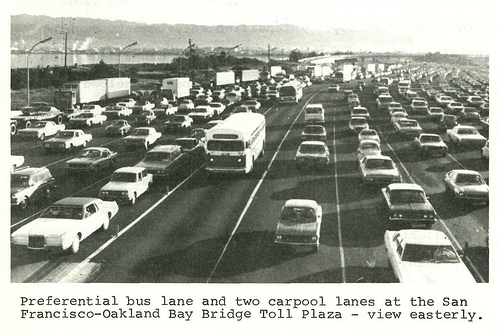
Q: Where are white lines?
A: On the street.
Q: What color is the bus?
A: White.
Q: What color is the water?
A: Gray.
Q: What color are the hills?
A: Gray.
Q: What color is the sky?
A: White.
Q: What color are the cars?
A: White.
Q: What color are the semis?
A: White.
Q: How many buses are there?
A: One.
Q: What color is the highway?
A: Gray.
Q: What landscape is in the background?
A: Mountains.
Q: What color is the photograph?
A: Black and white.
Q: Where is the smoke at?
A: Distant left.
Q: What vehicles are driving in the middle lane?
A: Busses.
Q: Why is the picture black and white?
A: Old.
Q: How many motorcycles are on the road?
A: 0.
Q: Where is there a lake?
A: Top left.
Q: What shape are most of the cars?
A: Rectangle.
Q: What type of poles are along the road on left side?
A: Light poles.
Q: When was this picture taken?
A: Long time ago.